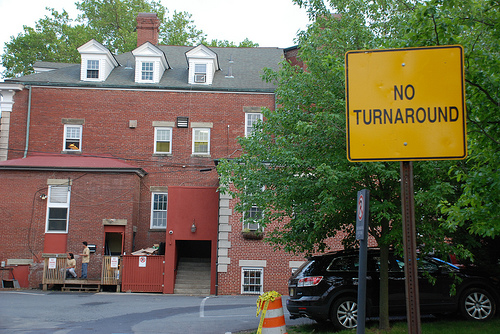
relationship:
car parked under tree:
[287, 245, 497, 329] [211, 0, 499, 325]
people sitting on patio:
[46, 231, 110, 286] [40, 252, 117, 286]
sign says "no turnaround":
[346, 46, 465, 163] [353, 84, 463, 124]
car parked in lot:
[287, 245, 497, 329] [4, 288, 304, 332]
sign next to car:
[346, 46, 465, 163] [287, 245, 497, 329]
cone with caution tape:
[255, 290, 291, 332] [256, 285, 278, 332]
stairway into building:
[174, 242, 216, 297] [19, 25, 374, 312]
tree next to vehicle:
[274, 76, 474, 220] [286, 243, 448, 297]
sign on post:
[346, 54, 470, 163] [393, 166, 423, 331]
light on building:
[174, 115, 190, 128] [3, 10, 413, 317]